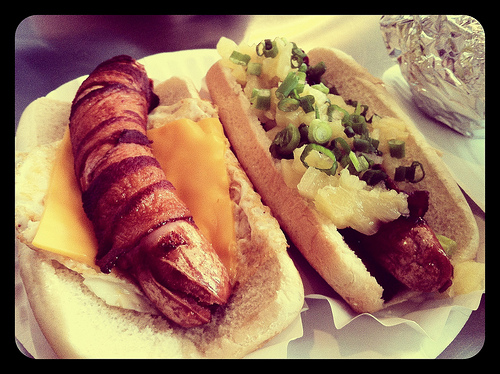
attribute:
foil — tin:
[380, 15, 485, 140]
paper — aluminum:
[376, 18, 489, 161]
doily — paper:
[286, 242, 486, 334]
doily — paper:
[14, 247, 313, 358]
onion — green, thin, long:
[218, 37, 250, 67]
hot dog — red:
[205, 34, 483, 316]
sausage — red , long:
[68, 54, 231, 327]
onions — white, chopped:
[301, 159, 416, 233]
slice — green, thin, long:
[328, 96, 391, 145]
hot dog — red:
[207, 46, 451, 281]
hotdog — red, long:
[244, 63, 451, 288]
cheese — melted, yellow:
[28, 114, 238, 281]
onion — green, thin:
[303, 55, 328, 78]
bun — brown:
[186, 153, 331, 354]